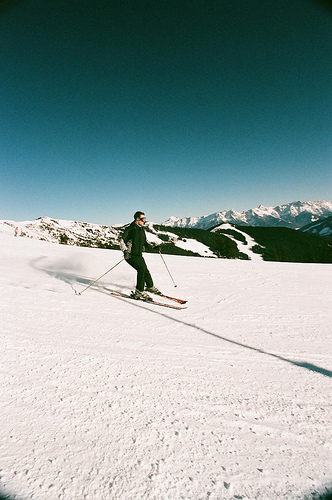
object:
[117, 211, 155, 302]
man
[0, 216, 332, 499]
hill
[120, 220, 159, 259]
winter jacket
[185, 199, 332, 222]
mountaintops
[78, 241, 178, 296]
ski pole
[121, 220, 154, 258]
black jacket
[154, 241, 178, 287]
poles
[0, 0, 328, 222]
sky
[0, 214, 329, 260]
mountain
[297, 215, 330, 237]
mountain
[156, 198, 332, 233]
mountain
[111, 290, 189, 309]
ski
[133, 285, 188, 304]
ski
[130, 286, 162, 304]
boots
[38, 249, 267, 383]
slope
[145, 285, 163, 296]
boot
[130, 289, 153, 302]
boot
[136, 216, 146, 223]
goggles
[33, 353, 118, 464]
ground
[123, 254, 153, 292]
pants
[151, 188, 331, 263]
mountains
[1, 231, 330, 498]
snow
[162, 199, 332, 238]
mountain tops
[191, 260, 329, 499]
downhill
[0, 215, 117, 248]
mountains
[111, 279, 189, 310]
skis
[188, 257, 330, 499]
hill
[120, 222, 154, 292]
clothes